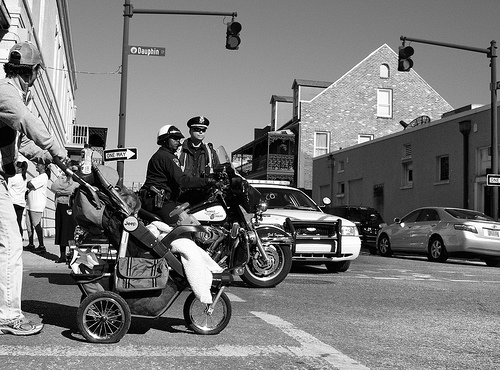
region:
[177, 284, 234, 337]
a black wheel on the stroller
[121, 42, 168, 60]
a street sign on the pole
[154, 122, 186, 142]
a white helmet on the man's head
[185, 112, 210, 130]
a black policeman's hat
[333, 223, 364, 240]
the head light of a car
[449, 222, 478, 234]
the tail light of a car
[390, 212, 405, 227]
a side view mirror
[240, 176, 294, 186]
lights on the police car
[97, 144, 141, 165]
a one way sign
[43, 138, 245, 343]
a stroller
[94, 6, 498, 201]
traffic lights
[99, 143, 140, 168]
one way sign on traffic light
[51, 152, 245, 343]
stroller with small child inside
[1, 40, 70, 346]
person in baseball cap pushing the stroller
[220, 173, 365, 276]
police car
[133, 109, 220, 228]
a cop standing next to another cop on a motorcycle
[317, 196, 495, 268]
cars parked on the right side of street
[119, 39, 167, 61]
street sign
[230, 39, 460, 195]
brick building with patio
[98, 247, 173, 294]
small bag hanging on stroller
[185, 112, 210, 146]
a head wearing a hat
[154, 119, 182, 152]
a head wearing a hat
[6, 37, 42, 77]
a head wearing a hat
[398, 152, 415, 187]
a window on a building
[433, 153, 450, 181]
a window on a building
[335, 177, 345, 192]
a window on a building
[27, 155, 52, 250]
a person standing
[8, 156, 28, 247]
a person standing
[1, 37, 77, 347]
a person standing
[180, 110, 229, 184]
a person standing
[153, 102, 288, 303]
the policeman is on a motorcycle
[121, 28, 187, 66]
the name of the street is Dauphin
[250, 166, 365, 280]
the police car is white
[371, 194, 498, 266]
the car is silver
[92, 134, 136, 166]
the sign says one way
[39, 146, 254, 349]
the baby is in the stroller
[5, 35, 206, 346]
a man is pushing the baby stroller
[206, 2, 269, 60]
there are only two lights in the traffic signal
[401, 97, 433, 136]
the building has a satellite dish on top of it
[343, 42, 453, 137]
the building is made of brick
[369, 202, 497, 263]
a vehicle in the street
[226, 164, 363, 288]
a vehicle in the street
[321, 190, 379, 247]
a vehicle in the street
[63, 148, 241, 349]
a vehicle in the street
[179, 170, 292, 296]
a vehicle in the street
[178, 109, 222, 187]
a person in the street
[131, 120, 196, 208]
a person in the street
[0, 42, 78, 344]
a person in the street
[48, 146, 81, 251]
a person in the street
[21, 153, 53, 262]
a person in the street